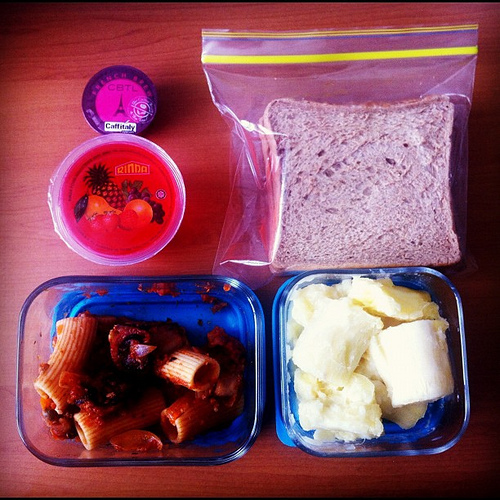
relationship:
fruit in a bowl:
[72, 163, 166, 232] [47, 133, 188, 269]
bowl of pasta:
[15, 275, 265, 466] [34, 316, 247, 451]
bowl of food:
[15, 275, 265, 466] [37, 280, 451, 446]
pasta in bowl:
[34, 316, 247, 451] [15, 275, 265, 466]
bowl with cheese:
[271, 270, 451, 448] [292, 303, 378, 381]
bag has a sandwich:
[254, 98, 465, 277] [259, 98, 462, 278]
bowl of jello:
[47, 133, 188, 269] [64, 141, 177, 260]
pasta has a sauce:
[34, 316, 247, 451] [109, 325, 169, 362]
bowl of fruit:
[15, 275, 265, 466] [72, 163, 166, 232]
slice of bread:
[263, 95, 463, 273] [260, 96, 462, 271]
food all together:
[37, 280, 451, 446] [27, 50, 477, 470]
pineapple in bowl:
[70, 190, 155, 240] [47, 133, 188, 269]